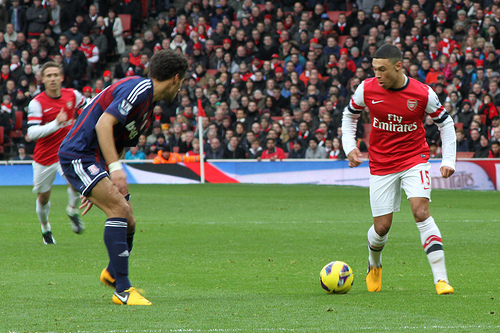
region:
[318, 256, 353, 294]
Yellow soccer ball on field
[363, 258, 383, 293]
Orange soccer cleat worn on right foot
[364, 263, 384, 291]
Soccer cleat on right foot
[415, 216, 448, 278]
Shin sock on leg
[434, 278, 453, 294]
Soccer cleat on left foot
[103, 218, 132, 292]
Blue shin sock on leg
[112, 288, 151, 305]
Nike soccer cleat being worn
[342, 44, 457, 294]
A soccer player playing soccer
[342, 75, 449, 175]
red soccer jersey being worn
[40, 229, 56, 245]
Black and white soccer cleat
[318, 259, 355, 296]
a yellow soccer ball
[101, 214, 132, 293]
tall blue socks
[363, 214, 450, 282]
tall white socks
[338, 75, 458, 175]
red shirt with white sleeves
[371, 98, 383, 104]
Nike logo on the shirt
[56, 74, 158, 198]
matching blue shirt and shorts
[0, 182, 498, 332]
grass on the soccer field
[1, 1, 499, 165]
people watching in the stands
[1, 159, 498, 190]
banner separating field from spectators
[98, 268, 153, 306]
yellow cleats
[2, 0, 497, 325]
Exterior, summertime, likely, daytime.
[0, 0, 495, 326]
Professional sport's field shown, with users and fans.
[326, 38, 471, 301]
Standing soccer player and yellow ball.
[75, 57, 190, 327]
Standing, slumped, soccer player.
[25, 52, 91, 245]
Running soccer player.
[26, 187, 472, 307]
High socks and bare knees on players.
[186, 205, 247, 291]
Meticulous, green field.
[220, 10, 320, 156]
Spectators packed tightly.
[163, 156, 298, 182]
Blue, white, red, stadium barrier.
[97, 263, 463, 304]
Identical, yellow shoes on two players.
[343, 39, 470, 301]
a soccer player wearing a red, white, and blue shirt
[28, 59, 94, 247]
a soccer player wearing a red, white, and blue shirt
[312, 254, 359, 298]
a yellow and black soccer ball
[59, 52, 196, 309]
a soccer player wearing a blue, red, and white shirt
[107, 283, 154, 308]
a yellow NIKE tennis shoe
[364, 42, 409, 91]
a head of a man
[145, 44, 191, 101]
a head of a man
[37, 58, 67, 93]
a head of a man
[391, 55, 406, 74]
the ear of a man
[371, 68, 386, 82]
the nose of a man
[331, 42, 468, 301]
soccer player in a red jersey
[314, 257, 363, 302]
yellow soccer ball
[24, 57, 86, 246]
soccer player in a red jersey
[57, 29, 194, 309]
soccer player in a blue and red jersey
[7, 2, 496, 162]
fans in the stands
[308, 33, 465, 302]
guy playing soccer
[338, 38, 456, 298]
Arsenal soccer player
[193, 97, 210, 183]
red flag on a white pole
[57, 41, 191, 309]
player in yellow cleats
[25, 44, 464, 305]
men playing soccer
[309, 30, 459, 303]
a man and a soccor ball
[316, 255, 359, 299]
the ball is blue and yellow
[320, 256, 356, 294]
yellow and blue soccer ball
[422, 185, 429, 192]
red Nike logo on white shorts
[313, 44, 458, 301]
man kicking soccer ball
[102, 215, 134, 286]
blue knee high Adidas socks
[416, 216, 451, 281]
knee high white Nike socks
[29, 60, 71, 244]
man running towards soccer ball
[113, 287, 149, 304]
yellow and black Nike shoes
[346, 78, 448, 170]
red and white jersey